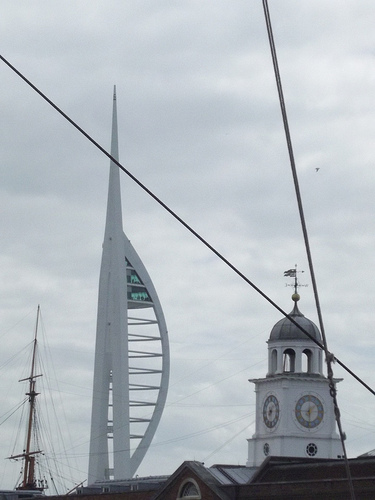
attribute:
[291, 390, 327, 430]
clock — large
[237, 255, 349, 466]
tower — bell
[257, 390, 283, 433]
clock — large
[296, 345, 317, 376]
arch — window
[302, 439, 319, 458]
circle — small, round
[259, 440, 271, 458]
circle — small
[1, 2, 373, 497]
sky — cloudy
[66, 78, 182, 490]
statue — sail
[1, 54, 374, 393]
wires — hanging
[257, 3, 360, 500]
wires — hanging